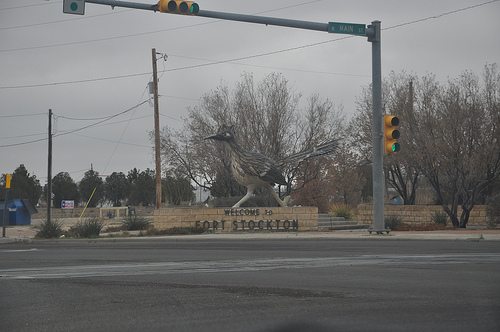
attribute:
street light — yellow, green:
[383, 113, 400, 156]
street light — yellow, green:
[159, 1, 199, 17]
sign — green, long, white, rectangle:
[326, 22, 368, 36]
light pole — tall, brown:
[151, 47, 164, 206]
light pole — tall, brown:
[46, 108, 51, 217]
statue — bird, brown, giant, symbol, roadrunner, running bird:
[207, 124, 344, 208]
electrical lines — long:
[2, 0, 499, 149]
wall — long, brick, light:
[33, 206, 320, 231]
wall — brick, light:
[358, 201, 497, 227]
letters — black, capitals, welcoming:
[196, 207, 300, 232]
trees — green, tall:
[0, 163, 194, 207]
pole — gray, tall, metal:
[86, 1, 392, 234]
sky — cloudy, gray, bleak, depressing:
[0, 0, 499, 207]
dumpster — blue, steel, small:
[1, 199, 38, 225]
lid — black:
[21, 197, 39, 215]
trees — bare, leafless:
[147, 62, 499, 228]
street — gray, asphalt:
[0, 239, 499, 330]